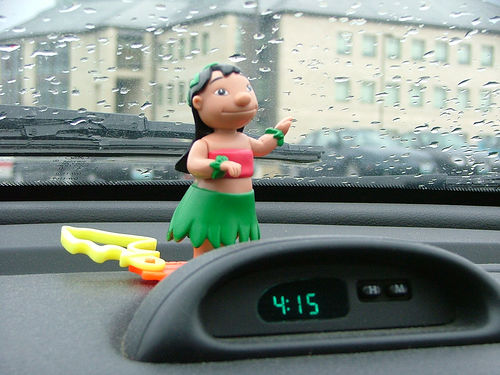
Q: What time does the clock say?
A: Four fifteen.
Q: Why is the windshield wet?
A: It's raining.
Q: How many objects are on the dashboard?
A: One.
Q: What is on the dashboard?
A: A toy.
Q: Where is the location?
A: On the road.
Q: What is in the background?
A: A large building.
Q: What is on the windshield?
A: Wipers.